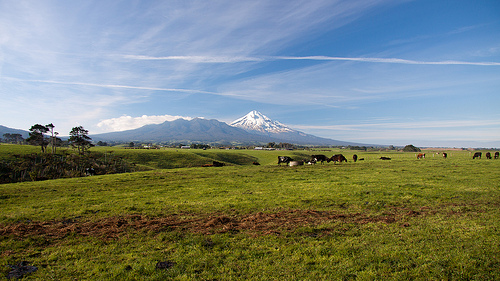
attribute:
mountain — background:
[114, 106, 306, 137]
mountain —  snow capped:
[82, 108, 311, 134]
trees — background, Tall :
[27, 121, 118, 163]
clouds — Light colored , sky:
[165, 31, 378, 71]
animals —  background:
[276, 143, 462, 187]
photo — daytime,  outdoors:
[4, 3, 463, 279]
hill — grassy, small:
[0, 145, 259, 187]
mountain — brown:
[57, 112, 295, 152]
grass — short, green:
[4, 147, 498, 278]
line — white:
[103, 53, 499, 70]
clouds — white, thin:
[3, 3, 497, 145]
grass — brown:
[0, 198, 495, 251]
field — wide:
[8, 147, 494, 278]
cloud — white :
[40, 42, 229, 98]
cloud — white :
[61, 57, 201, 105]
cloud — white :
[76, 54, 245, 105]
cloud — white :
[61, 46, 217, 123]